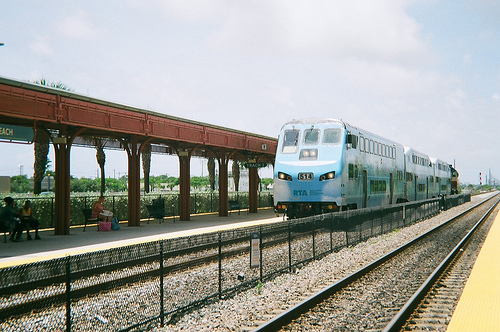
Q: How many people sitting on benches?
A: 3.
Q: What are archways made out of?
A: Steel.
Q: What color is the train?
A: Blue.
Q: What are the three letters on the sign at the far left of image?
A: ACH.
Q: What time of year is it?
A: Summer.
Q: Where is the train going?
A: To pick up passengers.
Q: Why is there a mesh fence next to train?
A: To keep people away.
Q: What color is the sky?
A: Blue.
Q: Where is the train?
A: On the tracks.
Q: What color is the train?
A: Blue.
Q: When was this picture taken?
A: Morning.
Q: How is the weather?
A: Clear.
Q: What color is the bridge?
A: Red.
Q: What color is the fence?
A: Black.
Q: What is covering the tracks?
A: Gravel.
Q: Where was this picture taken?
A: A railway.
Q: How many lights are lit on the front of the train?
A: Two.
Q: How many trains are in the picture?
A: One.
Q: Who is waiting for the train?
A: Passengers.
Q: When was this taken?
A: Daytime.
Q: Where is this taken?
A: Train station.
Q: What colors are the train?
A: Blue and white.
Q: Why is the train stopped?
A: To pick up passengers.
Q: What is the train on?
A: Train tracks.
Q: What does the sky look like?
A: Blue and cloudy.